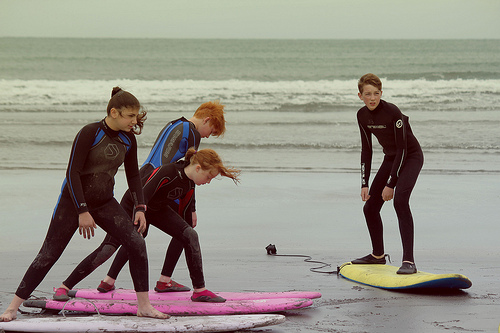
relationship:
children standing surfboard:
[350, 73, 424, 274] [336, 250, 475, 299]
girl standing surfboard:
[0, 87, 170, 322] [67, 281, 318, 306]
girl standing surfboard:
[53, 149, 226, 302] [29, 295, 312, 314]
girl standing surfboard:
[53, 149, 226, 302] [1, 310, 290, 330]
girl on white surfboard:
[50, 145, 240, 298] [0, 311, 290, 330]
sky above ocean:
[5, 1, 497, 40] [132, 27, 372, 116]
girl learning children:
[0, 87, 170, 322] [350, 73, 424, 274]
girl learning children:
[53, 149, 226, 302] [350, 73, 424, 274]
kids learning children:
[96, 102, 225, 293] [350, 73, 424, 274]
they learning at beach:
[0, 71, 427, 323] [11, 17, 497, 288]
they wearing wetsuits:
[0, 73, 424, 322] [332, 87, 454, 243]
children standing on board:
[350, 73, 424, 274] [339, 264, 472, 289]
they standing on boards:
[0, 73, 424, 322] [38, 273, 338, 316]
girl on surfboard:
[1, 82, 173, 325] [1, 311, 289, 332]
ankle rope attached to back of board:
[261, 240, 346, 280] [336, 251, 470, 296]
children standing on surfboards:
[5, 65, 493, 322] [1, 254, 496, 330]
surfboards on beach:
[1, 254, 496, 330] [0, 1, 499, 326]